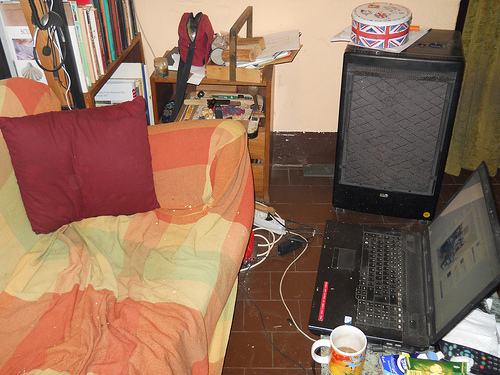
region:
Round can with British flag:
[346, 0, 414, 52]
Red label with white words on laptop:
[314, 278, 330, 323]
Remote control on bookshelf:
[162, 92, 176, 124]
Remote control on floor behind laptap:
[423, 335, 499, 374]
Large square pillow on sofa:
[0, 98, 160, 236]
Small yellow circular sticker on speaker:
[419, 208, 435, 223]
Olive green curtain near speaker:
[436, 0, 497, 180]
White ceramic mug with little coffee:
[304, 323, 374, 373]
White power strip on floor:
[248, 196, 290, 238]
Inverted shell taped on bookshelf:
[13, 57, 47, 82]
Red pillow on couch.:
[67, 90, 117, 232]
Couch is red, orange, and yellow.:
[67, 265, 164, 361]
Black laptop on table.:
[267, 197, 419, 360]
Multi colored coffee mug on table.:
[309, 315, 357, 372]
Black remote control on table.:
[433, 323, 485, 371]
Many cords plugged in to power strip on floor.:
[258, 195, 315, 363]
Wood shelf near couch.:
[166, 81, 286, 152]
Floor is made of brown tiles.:
[256, 267, 311, 368]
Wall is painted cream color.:
[288, 97, 321, 125]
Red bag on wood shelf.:
[169, 17, 221, 56]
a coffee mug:
[287, 309, 381, 373]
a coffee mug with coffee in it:
[302, 310, 376, 372]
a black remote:
[395, 317, 498, 373]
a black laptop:
[293, 138, 490, 363]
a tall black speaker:
[316, 18, 446, 239]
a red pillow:
[14, 86, 190, 222]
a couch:
[8, 67, 273, 374]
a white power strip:
[229, 191, 311, 266]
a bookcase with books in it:
[1, 0, 202, 126]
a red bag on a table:
[156, 4, 253, 99]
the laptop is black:
[311, 171, 492, 364]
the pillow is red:
[6, 91, 181, 236]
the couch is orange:
[0, 63, 286, 370]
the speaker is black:
[334, 39, 458, 254]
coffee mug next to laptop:
[309, 313, 370, 373]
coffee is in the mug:
[289, 313, 383, 370]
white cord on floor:
[245, 202, 335, 362]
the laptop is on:
[435, 148, 495, 319]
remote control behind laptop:
[426, 321, 497, 368]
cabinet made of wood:
[149, 21, 306, 213]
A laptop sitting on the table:
[325, 168, 498, 373]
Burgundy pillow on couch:
[3, 100, 180, 227]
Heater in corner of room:
[348, 29, 445, 237]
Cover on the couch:
[15, 93, 155, 363]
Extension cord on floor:
[254, 205, 320, 309]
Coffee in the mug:
[316, 320, 381, 373]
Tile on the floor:
[243, 308, 276, 365]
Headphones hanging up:
[26, 7, 72, 80]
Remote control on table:
[431, 325, 496, 372]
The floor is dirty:
[236, 295, 302, 370]